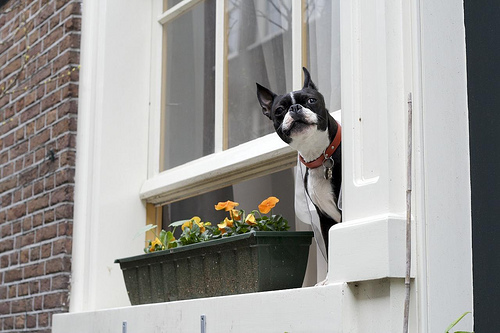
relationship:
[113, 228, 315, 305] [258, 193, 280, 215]
planter with flower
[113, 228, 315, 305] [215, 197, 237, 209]
planter with flower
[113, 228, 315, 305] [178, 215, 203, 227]
planter with flower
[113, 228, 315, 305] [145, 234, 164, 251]
planter with flower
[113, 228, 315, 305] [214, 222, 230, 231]
planter with flower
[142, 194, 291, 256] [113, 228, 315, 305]
flowers in planter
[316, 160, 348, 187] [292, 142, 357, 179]
metal tags on collar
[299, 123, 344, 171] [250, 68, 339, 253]
red collar on dog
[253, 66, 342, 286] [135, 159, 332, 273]
boston terrier in window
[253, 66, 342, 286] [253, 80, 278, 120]
boston terrier has ear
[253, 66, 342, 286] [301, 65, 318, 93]
boston terrier has ear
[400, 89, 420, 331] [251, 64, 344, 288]
stick next to dog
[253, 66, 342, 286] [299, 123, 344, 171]
boston terrier wearing a red collar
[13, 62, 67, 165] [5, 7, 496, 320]
bricks on building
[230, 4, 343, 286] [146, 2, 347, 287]
curtains inside window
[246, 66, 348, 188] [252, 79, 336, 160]
boston terrier has head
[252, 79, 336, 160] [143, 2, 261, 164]
head outside window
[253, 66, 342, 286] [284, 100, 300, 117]
boston terrier has nose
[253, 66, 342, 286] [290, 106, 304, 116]
boston terrier has nose